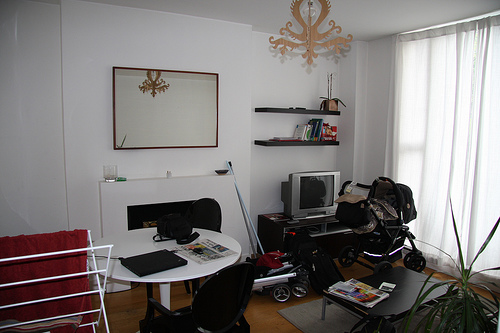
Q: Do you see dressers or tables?
A: Yes, there is a table.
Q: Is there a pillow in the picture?
A: No, there are no pillows.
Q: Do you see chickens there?
A: No, there are no chickens.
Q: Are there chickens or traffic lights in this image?
A: No, there are no chickens or traffic lights.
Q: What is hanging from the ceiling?
A: The light fixture is hanging from the ceiling.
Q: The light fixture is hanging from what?
A: The light fixture is hanging from the ceiling.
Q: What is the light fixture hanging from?
A: The light fixture is hanging from the ceiling.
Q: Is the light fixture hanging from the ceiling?
A: Yes, the light fixture is hanging from the ceiling.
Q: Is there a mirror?
A: Yes, there is a mirror.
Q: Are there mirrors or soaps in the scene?
A: Yes, there is a mirror.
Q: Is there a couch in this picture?
A: No, there are no couches.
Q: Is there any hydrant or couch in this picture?
A: No, there are no couches or fire hydrants.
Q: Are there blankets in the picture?
A: Yes, there is a blanket.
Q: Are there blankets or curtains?
A: Yes, there is a blanket.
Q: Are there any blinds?
A: No, there are no blinds.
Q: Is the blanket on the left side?
A: Yes, the blanket is on the left of the image.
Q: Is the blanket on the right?
A: No, the blanket is on the left of the image.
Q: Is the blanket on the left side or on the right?
A: The blanket is on the left of the image.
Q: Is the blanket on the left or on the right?
A: The blanket is on the left of the image.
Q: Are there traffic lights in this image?
A: No, there are no traffic lights.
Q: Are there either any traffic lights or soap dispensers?
A: No, there are no traffic lights or soap dispensers.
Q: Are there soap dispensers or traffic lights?
A: No, there are no traffic lights or soap dispensers.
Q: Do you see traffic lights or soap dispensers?
A: No, there are no traffic lights or soap dispensers.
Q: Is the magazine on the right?
A: Yes, the magazine is on the right of the image.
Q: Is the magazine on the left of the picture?
A: No, the magazine is on the right of the image.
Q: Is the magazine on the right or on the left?
A: The magazine is on the right of the image.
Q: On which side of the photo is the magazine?
A: The magazine is on the right of the image.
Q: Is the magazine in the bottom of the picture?
A: Yes, the magazine is in the bottom of the image.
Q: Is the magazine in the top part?
A: No, the magazine is in the bottom of the image.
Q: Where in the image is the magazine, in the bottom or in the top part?
A: The magazine is in the bottom of the image.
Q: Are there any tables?
A: Yes, there is a table.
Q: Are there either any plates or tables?
A: Yes, there is a table.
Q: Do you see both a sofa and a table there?
A: No, there is a table but no sofas.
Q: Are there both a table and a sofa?
A: No, there is a table but no sofas.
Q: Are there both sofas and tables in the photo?
A: No, there is a table but no sofas.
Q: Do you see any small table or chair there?
A: Yes, there is a small table.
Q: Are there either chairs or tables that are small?
A: Yes, the table is small.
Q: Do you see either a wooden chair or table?
A: Yes, there is a wood table.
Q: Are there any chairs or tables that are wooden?
A: Yes, the table is wooden.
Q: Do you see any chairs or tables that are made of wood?
A: Yes, the table is made of wood.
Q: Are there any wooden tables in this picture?
A: Yes, there is a wood table.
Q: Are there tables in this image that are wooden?
A: Yes, there is a table that is wooden.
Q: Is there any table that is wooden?
A: Yes, there is a table that is wooden.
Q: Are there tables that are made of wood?
A: Yes, there is a table that is made of wood.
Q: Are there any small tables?
A: Yes, there is a small table.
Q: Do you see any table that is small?
A: Yes, there is a table that is small.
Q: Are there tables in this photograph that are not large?
A: Yes, there is a small table.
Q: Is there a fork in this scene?
A: No, there are no forks.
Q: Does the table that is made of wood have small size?
A: Yes, the table is small.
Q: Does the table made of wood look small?
A: Yes, the table is small.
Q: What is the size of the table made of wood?
A: The table is small.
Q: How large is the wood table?
A: The table is small.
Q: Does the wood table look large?
A: No, the table is small.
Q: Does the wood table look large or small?
A: The table is small.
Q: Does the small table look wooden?
A: Yes, the table is wooden.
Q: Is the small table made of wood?
A: Yes, the table is made of wood.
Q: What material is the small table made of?
A: The table is made of wood.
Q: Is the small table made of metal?
A: No, the table is made of wood.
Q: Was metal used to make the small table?
A: No, the table is made of wood.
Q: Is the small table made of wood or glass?
A: The table is made of wood.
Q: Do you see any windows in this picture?
A: Yes, there is a window.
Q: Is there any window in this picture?
A: Yes, there is a window.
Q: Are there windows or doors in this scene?
A: Yes, there is a window.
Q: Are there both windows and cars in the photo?
A: No, there is a window but no cars.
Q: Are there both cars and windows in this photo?
A: No, there is a window but no cars.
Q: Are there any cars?
A: No, there are no cars.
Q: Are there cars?
A: No, there are no cars.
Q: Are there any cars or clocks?
A: No, there are no cars or clocks.